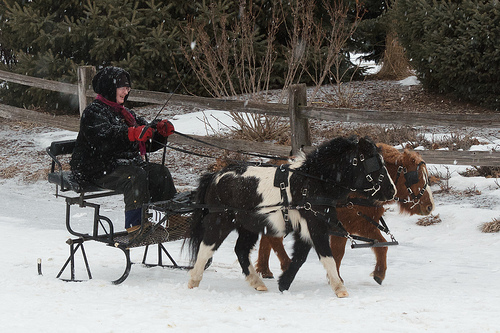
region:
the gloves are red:
[122, 117, 177, 148]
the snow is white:
[81, 295, 159, 327]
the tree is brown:
[192, 12, 323, 106]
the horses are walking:
[189, 135, 430, 289]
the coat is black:
[72, 92, 179, 205]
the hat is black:
[84, 57, 146, 109]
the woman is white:
[53, 48, 209, 243]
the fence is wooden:
[225, 80, 310, 166]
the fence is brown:
[177, 77, 306, 167]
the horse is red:
[389, 128, 461, 228]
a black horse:
[341, 138, 395, 205]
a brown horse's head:
[388, 153, 436, 200]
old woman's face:
[73, 63, 149, 110]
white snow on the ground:
[431, 265, 488, 318]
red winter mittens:
[132, 124, 153, 145]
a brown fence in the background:
[226, 87, 274, 126]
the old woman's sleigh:
[61, 198, 136, 276]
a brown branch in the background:
[171, 29, 317, 96]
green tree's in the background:
[37, 32, 207, 99]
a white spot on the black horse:
[231, 177, 311, 223]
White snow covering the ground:
[68, 296, 336, 331]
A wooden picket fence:
[5, 67, 71, 132]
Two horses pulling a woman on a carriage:
[47, 59, 433, 304]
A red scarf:
[88, 92, 134, 129]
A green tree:
[411, 10, 490, 101]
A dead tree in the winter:
[191, 25, 324, 84]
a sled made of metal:
[44, 149, 194, 286]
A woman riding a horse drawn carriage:
[60, 69, 188, 232]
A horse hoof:
[370, 270, 390, 287]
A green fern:
[17, 10, 174, 59]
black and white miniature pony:
[171, 135, 380, 304]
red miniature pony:
[288, 143, 448, 296]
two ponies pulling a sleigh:
[163, 127, 448, 292]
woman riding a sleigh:
[69, 80, 184, 237]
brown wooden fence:
[0, 86, 441, 171]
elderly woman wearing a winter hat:
[72, 65, 176, 225]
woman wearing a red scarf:
[68, 81, 159, 137]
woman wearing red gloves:
[102, 100, 196, 159]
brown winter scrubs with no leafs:
[180, 15, 395, 130]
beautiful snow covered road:
[11, 225, 446, 310]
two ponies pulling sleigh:
[187, 130, 441, 301]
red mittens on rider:
[124, 110, 181, 145]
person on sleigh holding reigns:
[63, 59, 190, 236]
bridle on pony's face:
[402, 183, 425, 210]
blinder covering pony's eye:
[360, 150, 385, 177]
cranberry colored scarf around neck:
[85, 90, 152, 145]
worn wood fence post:
[280, 75, 314, 141]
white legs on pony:
[192, 245, 265, 293]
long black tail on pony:
[176, 164, 217, 263]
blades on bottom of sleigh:
[63, 263, 133, 285]